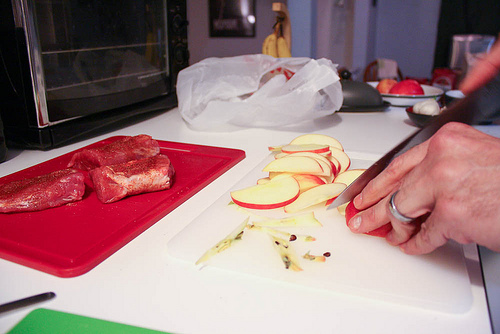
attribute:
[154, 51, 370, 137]
bag counter — plastic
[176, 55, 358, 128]
bag — white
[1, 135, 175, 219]
meat — three pieces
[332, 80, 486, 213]
knife — large, sharp, kitchen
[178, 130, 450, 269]
board — white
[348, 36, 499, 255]
person — holding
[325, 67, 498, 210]
knife — metal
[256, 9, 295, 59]
bananas — bunch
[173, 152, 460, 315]
board — clear, plastic, cutting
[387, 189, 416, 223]
ring — metal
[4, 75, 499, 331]
counter top — white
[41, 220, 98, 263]
cutting board — red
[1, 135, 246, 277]
cutting board — red, plastic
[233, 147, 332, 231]
apple — sliced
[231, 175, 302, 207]
apple — red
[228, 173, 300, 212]
slice — apple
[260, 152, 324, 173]
slice — apple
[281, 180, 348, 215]
slice — apple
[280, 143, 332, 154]
slice — apple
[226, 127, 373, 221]
apples — sliced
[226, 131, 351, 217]
apple — sliced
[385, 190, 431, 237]
ring — plain, silver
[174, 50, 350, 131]
bag — plastic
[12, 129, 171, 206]
meat — three cuts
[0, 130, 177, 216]
meat — red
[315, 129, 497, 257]
person — cutting